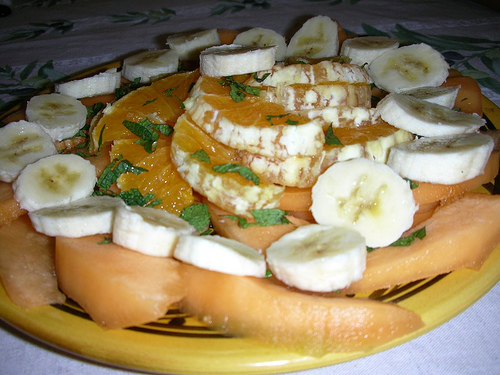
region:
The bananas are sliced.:
[17, 18, 486, 280]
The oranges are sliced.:
[92, 60, 356, 227]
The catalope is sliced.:
[1, 176, 483, 341]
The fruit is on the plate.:
[6, 15, 496, 357]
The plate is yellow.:
[10, 21, 498, 373]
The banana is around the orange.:
[0, 13, 453, 324]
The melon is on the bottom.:
[8, 12, 493, 362]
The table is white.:
[7, 3, 487, 373]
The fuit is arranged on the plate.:
[8, 8, 498, 368]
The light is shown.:
[6, 0, 490, 366]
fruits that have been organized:
[3, 33, 486, 305]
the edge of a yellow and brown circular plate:
[1, 254, 495, 373]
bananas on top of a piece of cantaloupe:
[285, 156, 487, 295]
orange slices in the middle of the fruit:
[58, 79, 353, 296]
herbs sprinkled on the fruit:
[92, 97, 332, 237]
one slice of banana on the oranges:
[189, 27, 316, 149]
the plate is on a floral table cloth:
[13, 6, 494, 134]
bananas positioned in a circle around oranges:
[17, 26, 482, 297]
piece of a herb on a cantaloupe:
[366, 218, 490, 285]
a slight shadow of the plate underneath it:
[3, 317, 223, 370]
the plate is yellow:
[74, 220, 260, 367]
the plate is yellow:
[351, 266, 481, 354]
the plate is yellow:
[48, 295, 142, 347]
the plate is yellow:
[125, 292, 267, 367]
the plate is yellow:
[163, 309, 239, 369]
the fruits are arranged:
[55, 45, 465, 372]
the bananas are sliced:
[32, 141, 135, 256]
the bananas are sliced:
[272, 195, 357, 297]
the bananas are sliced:
[342, 107, 427, 236]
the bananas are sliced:
[233, 107, 395, 219]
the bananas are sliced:
[361, 37, 451, 222]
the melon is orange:
[137, 230, 367, 365]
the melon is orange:
[345, 235, 497, 307]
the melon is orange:
[43, 225, 165, 341]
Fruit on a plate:
[56, 34, 313, 308]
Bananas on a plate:
[73, 189, 225, 256]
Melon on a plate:
[115, 257, 336, 344]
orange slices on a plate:
[123, 78, 300, 202]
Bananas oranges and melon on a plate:
[91, 125, 398, 291]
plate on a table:
[51, 28, 219, 195]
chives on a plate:
[123, 107, 170, 158]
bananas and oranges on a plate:
[88, 153, 233, 263]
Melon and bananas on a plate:
[37, 236, 326, 322]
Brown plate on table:
[365, 271, 475, 353]